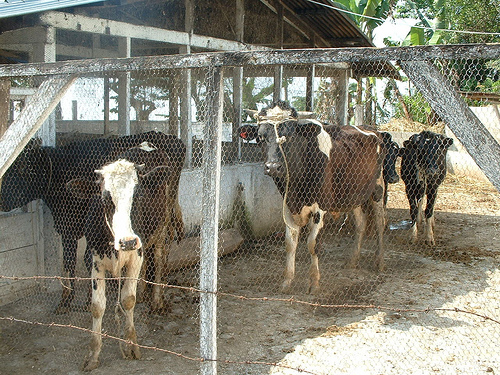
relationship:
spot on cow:
[305, 117, 333, 157] [228, 114, 399, 294]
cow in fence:
[213, 94, 399, 271] [0, 43, 500, 375]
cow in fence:
[369, 106, 475, 238] [0, 43, 500, 375]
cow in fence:
[53, 148, 208, 307] [0, 43, 500, 375]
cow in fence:
[0, 127, 186, 317] [0, 43, 500, 375]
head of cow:
[77, 159, 158, 267] [53, 148, 185, 374]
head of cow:
[233, 119, 321, 176] [234, 116, 413, 302]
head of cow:
[403, 129, 455, 190] [73, 127, 168, 316]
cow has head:
[380, 127, 407, 208] [376, 132, 404, 182]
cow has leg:
[228, 114, 399, 294] [304, 204, 336, 295]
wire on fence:
[7, 270, 495, 373] [4, 57, 498, 368]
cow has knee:
[53, 148, 185, 374] [116, 292, 136, 312]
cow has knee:
[53, 148, 185, 374] [85, 298, 106, 320]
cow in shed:
[0, 127, 186, 311] [2, 0, 499, 371]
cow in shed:
[53, 148, 185, 374] [2, 0, 499, 371]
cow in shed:
[228, 114, 399, 294] [2, 0, 499, 371]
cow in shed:
[373, 127, 406, 208] [2, 0, 499, 371]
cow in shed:
[394, 129, 455, 247] [2, 0, 499, 371]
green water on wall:
[226, 172, 262, 243] [161, 158, 290, 282]